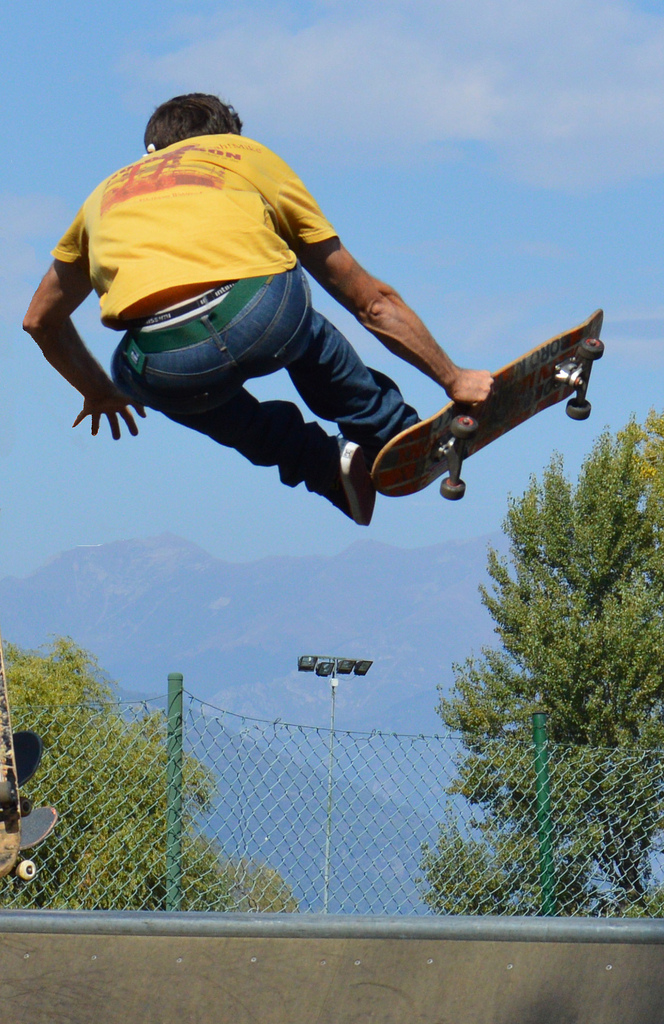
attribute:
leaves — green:
[494, 563, 562, 601]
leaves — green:
[641, 698, 659, 738]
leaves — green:
[553, 685, 591, 766]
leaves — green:
[619, 562, 628, 643]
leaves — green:
[117, 841, 146, 887]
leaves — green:
[502, 601, 538, 651]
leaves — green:
[591, 717, 604, 762]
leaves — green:
[573, 842, 609, 878]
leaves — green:
[494, 807, 547, 873]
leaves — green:
[461, 804, 484, 878]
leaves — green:
[590, 673, 648, 765]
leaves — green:
[552, 599, 618, 687]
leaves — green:
[111, 815, 126, 850]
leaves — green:
[178, 842, 286, 916]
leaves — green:
[90, 703, 168, 808]